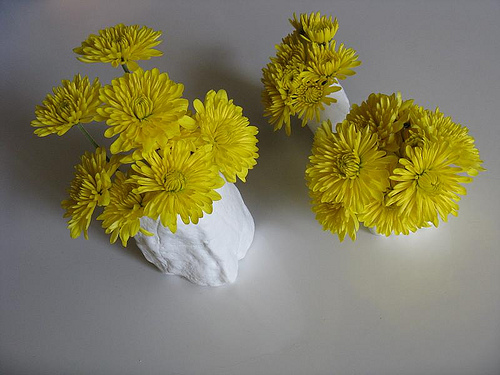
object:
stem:
[120, 56, 130, 74]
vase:
[295, 77, 351, 133]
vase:
[367, 223, 381, 236]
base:
[0, 0, 498, 372]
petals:
[360, 155, 388, 177]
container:
[133, 171, 256, 287]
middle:
[126, 93, 154, 120]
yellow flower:
[71, 23, 164, 74]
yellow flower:
[30, 73, 102, 137]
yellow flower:
[60, 147, 126, 240]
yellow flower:
[122, 139, 225, 234]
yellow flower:
[98, 67, 199, 153]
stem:
[77, 123, 121, 172]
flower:
[302, 93, 487, 245]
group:
[303, 92, 487, 243]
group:
[259, 11, 361, 135]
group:
[29, 23, 256, 286]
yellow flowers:
[303, 117, 398, 215]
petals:
[116, 77, 193, 105]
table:
[0, 0, 499, 375]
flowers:
[260, 10, 362, 136]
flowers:
[31, 24, 259, 248]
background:
[2, 217, 498, 372]